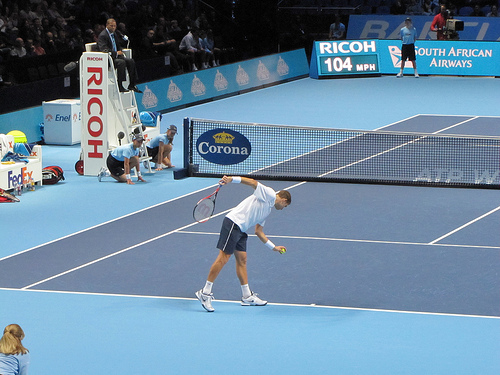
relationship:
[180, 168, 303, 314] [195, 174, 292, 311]
man a man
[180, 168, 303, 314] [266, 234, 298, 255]
man has a ball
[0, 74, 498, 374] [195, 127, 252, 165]
court has an advertisement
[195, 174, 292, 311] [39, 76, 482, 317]
man on a tennis court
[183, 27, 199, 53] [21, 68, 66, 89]
spectator in a bleacher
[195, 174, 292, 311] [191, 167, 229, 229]
man has a racket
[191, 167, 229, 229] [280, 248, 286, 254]
racket has ball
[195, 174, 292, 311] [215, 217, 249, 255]
man wears shorts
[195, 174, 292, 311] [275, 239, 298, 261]
man holds a ball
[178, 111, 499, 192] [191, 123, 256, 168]
tennis net holds a logo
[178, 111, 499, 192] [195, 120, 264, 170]
tennis net holds a brand logo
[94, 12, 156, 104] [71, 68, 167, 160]
man in an elevated seat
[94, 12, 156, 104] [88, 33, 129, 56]
man in a suit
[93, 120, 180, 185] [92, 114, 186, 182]
people in a seat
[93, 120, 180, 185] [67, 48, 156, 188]
people in a base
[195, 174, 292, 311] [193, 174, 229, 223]
man swinging racket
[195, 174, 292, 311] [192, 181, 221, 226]
man swinging racket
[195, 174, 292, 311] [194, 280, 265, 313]
man wears shoes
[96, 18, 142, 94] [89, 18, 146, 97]
man wearing a suit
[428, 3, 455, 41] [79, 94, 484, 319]
man recording ten event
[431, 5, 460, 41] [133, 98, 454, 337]
man standing in back of a tennis court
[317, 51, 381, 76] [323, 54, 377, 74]
display shows 104 mph